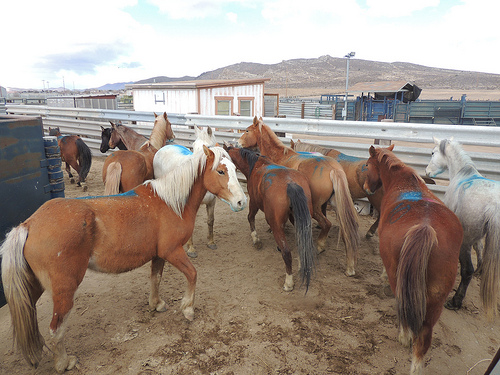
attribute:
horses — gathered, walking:
[15, 119, 499, 346]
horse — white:
[154, 121, 217, 177]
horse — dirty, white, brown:
[4, 150, 248, 352]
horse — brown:
[355, 148, 455, 352]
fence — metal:
[7, 103, 499, 208]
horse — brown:
[238, 141, 315, 284]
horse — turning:
[50, 126, 95, 175]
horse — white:
[426, 137, 499, 304]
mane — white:
[146, 143, 228, 219]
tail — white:
[5, 214, 40, 316]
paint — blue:
[461, 173, 494, 190]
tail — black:
[286, 184, 318, 280]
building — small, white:
[129, 77, 263, 115]